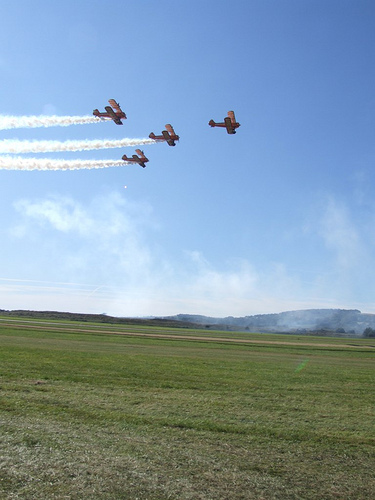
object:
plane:
[208, 111, 240, 135]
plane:
[149, 124, 180, 147]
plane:
[93, 99, 127, 125]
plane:
[122, 148, 149, 168]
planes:
[93, 98, 242, 168]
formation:
[93, 96, 241, 169]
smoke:
[0, 115, 153, 172]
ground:
[0, 315, 375, 500]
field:
[3, 313, 374, 497]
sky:
[0, 0, 375, 315]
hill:
[154, 308, 375, 334]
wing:
[108, 98, 127, 119]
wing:
[104, 106, 123, 126]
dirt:
[3, 317, 374, 354]